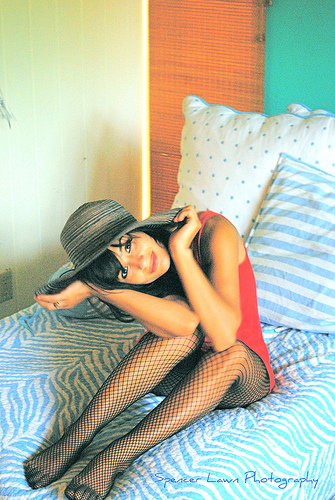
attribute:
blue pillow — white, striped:
[240, 152, 333, 341]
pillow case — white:
[173, 167, 268, 195]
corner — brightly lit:
[114, 2, 176, 227]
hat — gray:
[27, 186, 208, 309]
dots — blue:
[223, 157, 241, 183]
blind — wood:
[149, 0, 264, 219]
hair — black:
[72, 229, 196, 324]